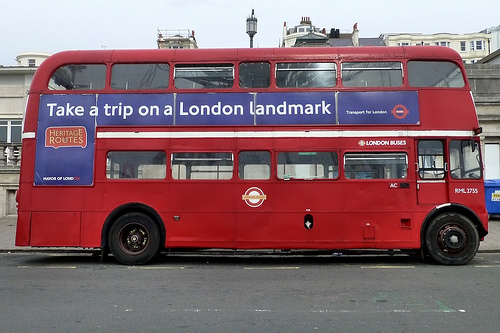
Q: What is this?
A: A twin bus.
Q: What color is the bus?
A: Red.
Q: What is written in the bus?
A: Take a trip on a London landmark.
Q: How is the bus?
A: Motionless.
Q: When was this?
A: Daytime.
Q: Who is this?
A: No one.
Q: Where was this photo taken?
A: On the street.